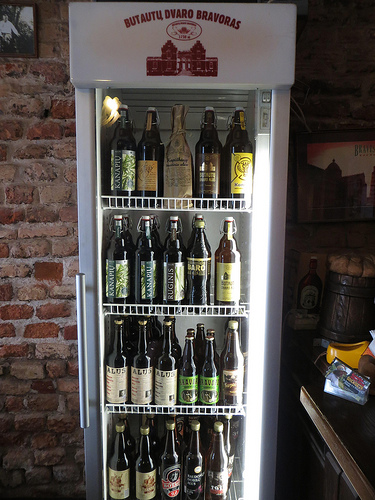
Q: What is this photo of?
A: Beverages.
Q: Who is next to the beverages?
A: Noone.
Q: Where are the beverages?
A: In a Refrigerator.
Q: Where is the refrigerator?
A: Inside a store.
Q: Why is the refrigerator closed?
A: To keep the beverages cold.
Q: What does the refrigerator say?
A: Butautu Dvaro Bravoras.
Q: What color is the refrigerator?
A: White.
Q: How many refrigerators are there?
A: One.